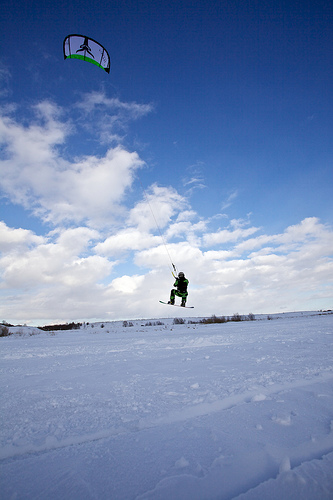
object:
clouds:
[0, 39, 331, 323]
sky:
[0, 0, 333, 324]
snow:
[0, 314, 333, 500]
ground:
[0, 311, 332, 499]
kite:
[63, 34, 111, 76]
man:
[168, 272, 190, 307]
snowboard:
[159, 301, 194, 309]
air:
[0, 0, 333, 327]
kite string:
[137, 173, 178, 279]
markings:
[13, 384, 331, 498]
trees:
[0, 311, 332, 338]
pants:
[170, 289, 188, 304]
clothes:
[170, 277, 190, 305]